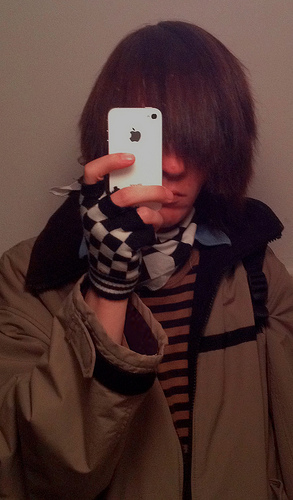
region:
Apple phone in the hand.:
[101, 106, 164, 198]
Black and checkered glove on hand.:
[74, 173, 155, 302]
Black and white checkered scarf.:
[70, 92, 232, 286]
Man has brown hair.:
[65, 97, 261, 248]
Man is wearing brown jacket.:
[2, 17, 290, 498]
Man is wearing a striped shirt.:
[0, 18, 291, 458]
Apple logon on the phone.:
[125, 125, 143, 143]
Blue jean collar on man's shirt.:
[46, 29, 281, 260]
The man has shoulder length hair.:
[79, 19, 252, 234]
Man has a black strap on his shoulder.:
[69, 78, 289, 327]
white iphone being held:
[87, 101, 169, 215]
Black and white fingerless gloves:
[63, 178, 156, 302]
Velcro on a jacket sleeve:
[64, 317, 165, 398]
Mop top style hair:
[60, 38, 266, 203]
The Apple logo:
[124, 125, 144, 145]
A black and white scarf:
[124, 222, 204, 291]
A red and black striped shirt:
[122, 263, 209, 459]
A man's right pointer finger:
[72, 150, 136, 189]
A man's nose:
[150, 139, 191, 181]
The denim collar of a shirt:
[184, 212, 239, 255]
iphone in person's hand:
[105, 96, 175, 216]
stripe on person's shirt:
[164, 404, 191, 411]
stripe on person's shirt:
[172, 416, 188, 432]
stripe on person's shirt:
[162, 382, 187, 399]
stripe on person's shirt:
[158, 385, 189, 394]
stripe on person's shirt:
[158, 368, 183, 381]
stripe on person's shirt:
[165, 337, 186, 345]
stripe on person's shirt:
[157, 319, 185, 324]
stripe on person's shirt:
[156, 286, 189, 296]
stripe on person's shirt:
[163, 350, 186, 360]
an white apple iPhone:
[105, 104, 161, 189]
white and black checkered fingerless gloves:
[80, 177, 154, 300]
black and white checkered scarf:
[140, 209, 203, 285]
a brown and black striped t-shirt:
[169, 247, 199, 435]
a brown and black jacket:
[193, 199, 292, 497]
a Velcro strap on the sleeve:
[68, 312, 156, 398]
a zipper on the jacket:
[264, 230, 285, 247]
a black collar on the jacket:
[24, 188, 79, 293]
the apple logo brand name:
[129, 126, 141, 142]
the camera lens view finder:
[150, 112, 157, 118]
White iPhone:
[108, 108, 162, 195]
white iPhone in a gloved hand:
[82, 106, 174, 297]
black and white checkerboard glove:
[80, 183, 152, 297]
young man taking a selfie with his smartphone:
[6, 19, 283, 498]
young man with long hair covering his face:
[1, 21, 291, 499]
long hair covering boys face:
[82, 19, 256, 238]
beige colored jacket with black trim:
[5, 204, 290, 489]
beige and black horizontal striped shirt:
[141, 250, 197, 458]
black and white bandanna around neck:
[26, 180, 195, 289]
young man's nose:
[164, 152, 184, 178]